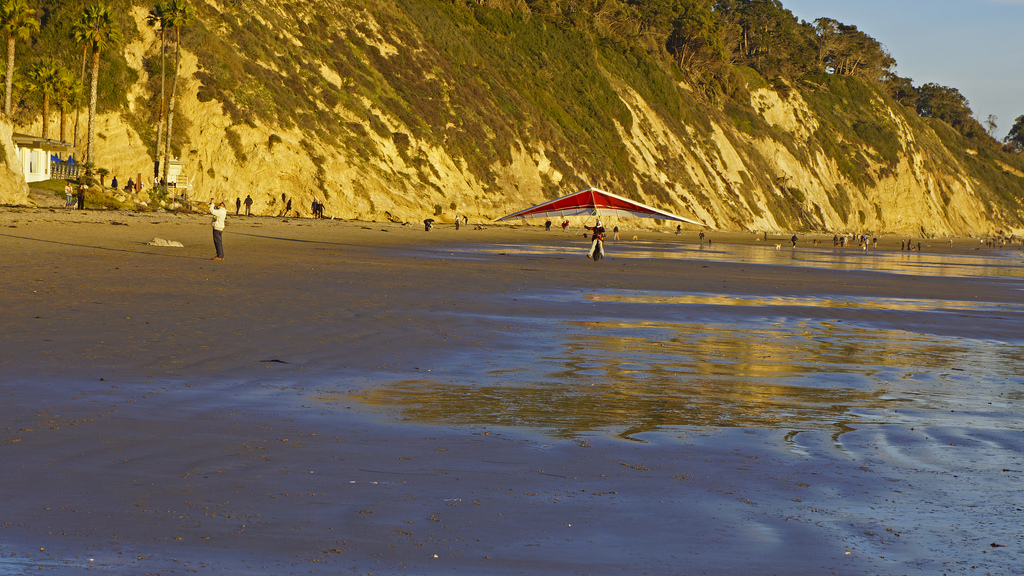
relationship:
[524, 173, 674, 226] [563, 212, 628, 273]
kite near person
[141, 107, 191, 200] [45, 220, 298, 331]
tall palm trees near a beach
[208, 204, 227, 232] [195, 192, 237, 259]
shirt on person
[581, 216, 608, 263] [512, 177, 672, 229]
person with kite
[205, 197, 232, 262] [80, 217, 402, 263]
person on sand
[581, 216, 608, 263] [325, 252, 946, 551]
person by water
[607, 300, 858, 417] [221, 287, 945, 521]
reflections in water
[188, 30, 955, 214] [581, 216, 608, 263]
cliff by person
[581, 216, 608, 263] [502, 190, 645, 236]
person with kite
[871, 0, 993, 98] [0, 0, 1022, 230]
sky by cliff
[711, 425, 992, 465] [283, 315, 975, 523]
waves in water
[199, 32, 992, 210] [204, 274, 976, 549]
hillside by water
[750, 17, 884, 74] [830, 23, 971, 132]
leaves on trees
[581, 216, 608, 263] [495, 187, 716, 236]
person with kite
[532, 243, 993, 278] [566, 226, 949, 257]
reflection on sand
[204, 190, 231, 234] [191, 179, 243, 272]
shirt on person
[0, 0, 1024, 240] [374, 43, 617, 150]
hillside with grass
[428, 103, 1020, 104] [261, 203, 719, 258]
trees on a hillside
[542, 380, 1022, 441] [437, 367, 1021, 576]
ripples in surface of sand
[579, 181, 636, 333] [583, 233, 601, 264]
person wearing khaki pants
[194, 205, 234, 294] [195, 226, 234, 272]
person wearing dark pants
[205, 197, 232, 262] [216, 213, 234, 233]
person wearing white shirt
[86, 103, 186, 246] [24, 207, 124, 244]
umbrellas near building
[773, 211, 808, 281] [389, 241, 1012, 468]
person wearing all dark clothing in distance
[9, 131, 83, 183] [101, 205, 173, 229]
building near blue umbrellas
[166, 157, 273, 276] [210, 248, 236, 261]
person wearing brown shoes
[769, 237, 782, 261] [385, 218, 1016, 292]
tan colored dog walking on beach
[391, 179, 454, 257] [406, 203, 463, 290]
person on beach bending over